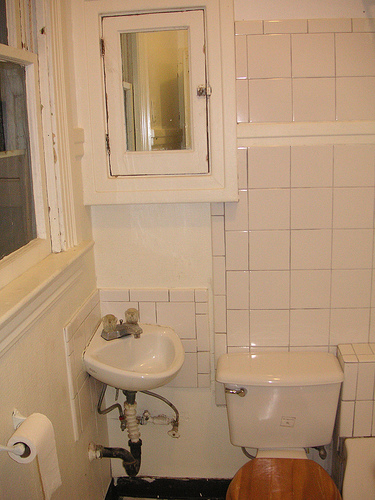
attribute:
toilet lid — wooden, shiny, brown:
[226, 457, 342, 499]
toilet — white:
[215, 351, 343, 498]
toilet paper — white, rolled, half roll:
[8, 414, 63, 500]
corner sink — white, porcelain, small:
[82, 309, 183, 393]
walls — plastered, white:
[64, 288, 212, 442]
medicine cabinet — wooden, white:
[71, 1, 239, 209]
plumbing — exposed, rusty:
[87, 381, 179, 478]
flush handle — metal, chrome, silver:
[224, 386, 247, 398]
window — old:
[0, 1, 52, 289]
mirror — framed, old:
[119, 29, 190, 150]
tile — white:
[99, 18, 372, 440]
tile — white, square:
[247, 188, 292, 231]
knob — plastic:
[124, 310, 140, 324]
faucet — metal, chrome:
[102, 308, 144, 342]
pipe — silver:
[239, 447, 255, 460]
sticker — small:
[280, 416, 296, 428]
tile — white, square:
[247, 146, 292, 191]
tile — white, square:
[290, 146, 334, 188]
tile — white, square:
[290, 188, 332, 230]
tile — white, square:
[332, 145, 374, 187]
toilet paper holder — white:
[1, 410, 30, 455]